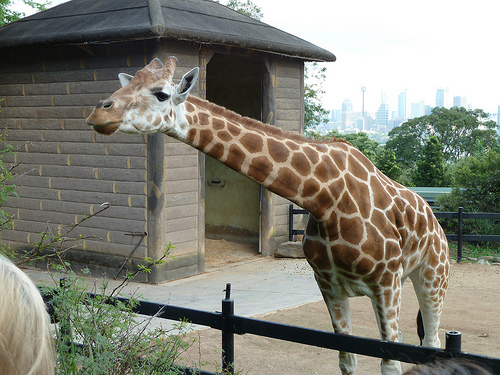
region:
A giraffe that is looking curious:
[48, 26, 236, 156]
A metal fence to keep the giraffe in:
[105, 287, 288, 372]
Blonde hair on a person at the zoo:
[7, 246, 67, 373]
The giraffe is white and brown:
[319, 184, 435, 277]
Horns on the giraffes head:
[132, 51, 176, 79]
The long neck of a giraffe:
[165, 87, 346, 220]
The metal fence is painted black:
[158, 289, 325, 373]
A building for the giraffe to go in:
[23, 30, 190, 259]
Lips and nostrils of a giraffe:
[80, 94, 115, 139]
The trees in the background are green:
[415, 102, 498, 167]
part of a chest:
[312, 215, 354, 315]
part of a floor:
[271, 343, 298, 371]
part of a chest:
[335, 225, 380, 280]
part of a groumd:
[288, 343, 307, 356]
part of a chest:
[341, 257, 372, 326]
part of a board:
[276, 318, 293, 345]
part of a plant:
[89, 318, 119, 365]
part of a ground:
[248, 319, 283, 369]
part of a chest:
[302, 195, 349, 257]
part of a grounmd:
[260, 341, 273, 360]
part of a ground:
[261, 341, 278, 365]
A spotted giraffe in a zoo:
[87, 38, 450, 373]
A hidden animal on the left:
[0, 255, 57, 373]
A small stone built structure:
[0, 0, 337, 285]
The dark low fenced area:
[25, 209, 498, 374]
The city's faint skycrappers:
[304, 82, 498, 163]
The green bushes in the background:
[229, 2, 497, 255]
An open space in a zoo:
[48, 258, 498, 373]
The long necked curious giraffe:
[82, 55, 452, 373]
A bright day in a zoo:
[0, 0, 498, 374]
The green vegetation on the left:
[0, 144, 237, 373]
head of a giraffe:
[87, 25, 224, 165]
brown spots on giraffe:
[315, 172, 411, 265]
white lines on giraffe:
[325, 191, 415, 266]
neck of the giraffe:
[172, 105, 353, 197]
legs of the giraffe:
[292, 280, 458, 335]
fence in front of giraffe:
[126, 275, 241, 370]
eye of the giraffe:
[146, 77, 171, 112]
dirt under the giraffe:
[437, 285, 492, 330]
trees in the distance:
[395, 101, 485, 161]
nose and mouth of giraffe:
[66, 87, 133, 145]